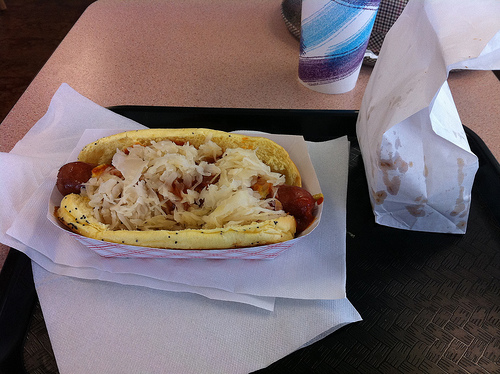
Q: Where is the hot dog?
A: In the plate.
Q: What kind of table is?
A: Wooden.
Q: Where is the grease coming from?
A: Thorough.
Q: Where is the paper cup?
A: On top of table.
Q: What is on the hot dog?
A: Sauerkraut.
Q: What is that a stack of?
A: White napkins.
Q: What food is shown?
A: Sausage.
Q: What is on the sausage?
A: Sauerkraut.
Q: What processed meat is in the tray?
A: Hot Dog.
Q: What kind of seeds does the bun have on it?
A: Poppy seed.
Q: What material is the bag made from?
A: Paper.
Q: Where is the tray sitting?
A: On a napkin.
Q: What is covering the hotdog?
A: Sauerkraut.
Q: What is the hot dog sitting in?
A: A bun.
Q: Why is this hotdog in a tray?
A: To be eaten.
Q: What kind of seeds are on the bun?
A: Poppy seeds.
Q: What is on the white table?
A: Black tray.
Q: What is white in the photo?
A: Tissue.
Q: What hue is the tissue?
A: White.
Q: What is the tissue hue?
A: White.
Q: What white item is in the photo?
A: Tissue.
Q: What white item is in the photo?
A: Tissue.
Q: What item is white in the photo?
A: Tissue.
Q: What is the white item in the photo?
A: Tissue.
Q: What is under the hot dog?
A: White tissue.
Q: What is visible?
A: A hot dog.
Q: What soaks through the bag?
A: Grease.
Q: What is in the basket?
A: A hot dog.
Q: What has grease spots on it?
A: A white bag.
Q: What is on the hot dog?
A: Sauerkraut.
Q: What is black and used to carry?
A: The tray.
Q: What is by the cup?
A: A hat.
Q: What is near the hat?
A: A cup.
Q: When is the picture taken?
A: Daytime.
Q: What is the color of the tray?
A: Black.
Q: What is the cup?
A: Blue and white.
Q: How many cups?
A: 1.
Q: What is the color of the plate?
A: White.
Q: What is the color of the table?
A: Red.